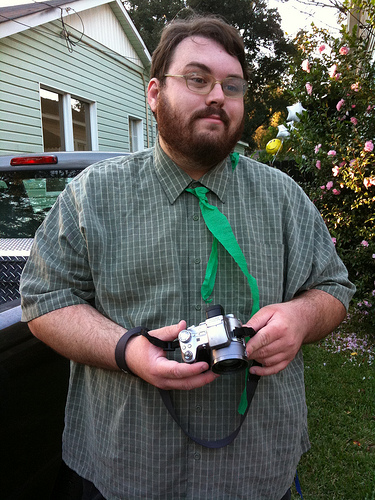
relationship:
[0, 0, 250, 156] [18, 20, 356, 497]
building in back of man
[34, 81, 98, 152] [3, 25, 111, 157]
window on building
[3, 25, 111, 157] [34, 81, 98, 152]
building with window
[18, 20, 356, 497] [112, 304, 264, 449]
man holding camera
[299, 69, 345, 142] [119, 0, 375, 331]
roses on bush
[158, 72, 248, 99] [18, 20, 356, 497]
eyeglasses on man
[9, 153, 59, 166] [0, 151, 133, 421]
red light on truck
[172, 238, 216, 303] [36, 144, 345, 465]
buttons on shirt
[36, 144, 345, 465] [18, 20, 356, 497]
shirt on man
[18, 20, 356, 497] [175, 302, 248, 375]
man with camera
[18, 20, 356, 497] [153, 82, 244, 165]
man with beard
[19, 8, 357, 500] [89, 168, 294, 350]
man with shirt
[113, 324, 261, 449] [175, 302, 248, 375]
strap on camera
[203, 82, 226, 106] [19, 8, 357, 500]
nose on man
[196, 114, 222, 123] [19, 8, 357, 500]
mouth on man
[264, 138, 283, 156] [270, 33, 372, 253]
yellow flower on bush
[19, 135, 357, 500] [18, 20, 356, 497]
shirt on man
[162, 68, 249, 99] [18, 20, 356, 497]
eyeglasses on man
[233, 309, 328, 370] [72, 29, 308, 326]
hand on man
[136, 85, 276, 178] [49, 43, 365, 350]
beard on man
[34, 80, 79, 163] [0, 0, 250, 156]
window on building